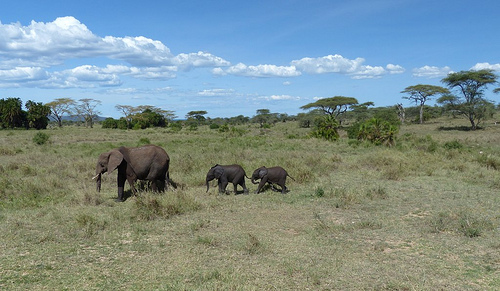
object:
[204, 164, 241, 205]
elephant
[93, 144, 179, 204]
elephant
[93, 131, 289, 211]
elephants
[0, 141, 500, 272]
field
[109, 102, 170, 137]
tree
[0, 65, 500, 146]
trees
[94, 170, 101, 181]
tusk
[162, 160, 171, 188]
tail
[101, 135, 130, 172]
ear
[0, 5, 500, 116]
sky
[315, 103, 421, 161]
bushes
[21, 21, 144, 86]
clouds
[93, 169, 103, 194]
trunk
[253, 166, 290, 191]
elephant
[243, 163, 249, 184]
tail